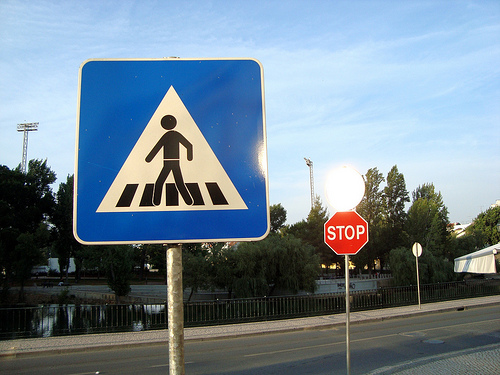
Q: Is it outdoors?
A: Yes, it is outdoors.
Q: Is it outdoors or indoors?
A: It is outdoors.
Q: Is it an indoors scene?
A: No, it is outdoors.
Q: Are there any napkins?
A: No, there are no napkins.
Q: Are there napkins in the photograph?
A: No, there are no napkins.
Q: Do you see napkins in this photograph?
A: No, there are no napkins.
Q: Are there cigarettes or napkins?
A: No, there are no napkins or cigarettes.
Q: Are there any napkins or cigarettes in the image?
A: No, there are no napkins or cigarettes.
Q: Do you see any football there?
A: No, there are no footballs.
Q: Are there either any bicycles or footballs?
A: No, there are no footballs or bicycles.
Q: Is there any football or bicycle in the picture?
A: No, there are no footballs or bicycles.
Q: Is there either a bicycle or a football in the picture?
A: No, there are no footballs or bicycles.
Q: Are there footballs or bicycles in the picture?
A: No, there are no footballs or bicycles.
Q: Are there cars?
A: No, there are no cars.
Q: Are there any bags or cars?
A: No, there are no cars or bags.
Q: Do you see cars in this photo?
A: No, there are no cars.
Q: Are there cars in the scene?
A: No, there are no cars.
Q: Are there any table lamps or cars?
A: No, there are no cars or table lamps.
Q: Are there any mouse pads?
A: No, there are no mouse pads.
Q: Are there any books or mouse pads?
A: No, there are no mouse pads or books.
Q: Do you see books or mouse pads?
A: No, there are no mouse pads or books.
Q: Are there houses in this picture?
A: No, there are no houses.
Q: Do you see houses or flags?
A: No, there are no houses or flags.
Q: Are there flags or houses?
A: No, there are no houses or flags.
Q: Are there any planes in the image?
A: No, there are no planes.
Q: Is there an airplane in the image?
A: No, there are no airplanes.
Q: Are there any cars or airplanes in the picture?
A: No, there are no airplanes or cars.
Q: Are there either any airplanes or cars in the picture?
A: No, there are no airplanes or cars.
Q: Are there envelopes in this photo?
A: No, there are no envelopes.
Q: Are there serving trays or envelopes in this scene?
A: No, there are no envelopes or serving trays.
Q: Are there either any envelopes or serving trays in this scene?
A: No, there are no envelopes or serving trays.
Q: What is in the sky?
A: The clouds are in the sky.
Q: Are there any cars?
A: No, there are no cars.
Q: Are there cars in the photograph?
A: No, there are no cars.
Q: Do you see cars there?
A: No, there are no cars.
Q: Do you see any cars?
A: No, there are no cars.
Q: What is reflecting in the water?
A: The tree is reflecting in the water.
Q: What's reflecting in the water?
A: The tree is reflecting in the water.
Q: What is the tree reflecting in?
A: The tree is reflecting in the water.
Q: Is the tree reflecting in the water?
A: Yes, the tree is reflecting in the water.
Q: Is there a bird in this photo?
A: No, there are no birds.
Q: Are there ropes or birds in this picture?
A: No, there are no birds or ropes.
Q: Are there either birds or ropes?
A: No, there are no birds or ropes.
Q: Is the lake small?
A: Yes, the lake is small.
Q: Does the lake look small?
A: Yes, the lake is small.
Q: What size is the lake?
A: The lake is small.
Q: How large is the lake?
A: The lake is small.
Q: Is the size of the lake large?
A: No, the lake is small.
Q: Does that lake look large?
A: No, the lake is small.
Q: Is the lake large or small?
A: The lake is small.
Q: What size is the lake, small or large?
A: The lake is small.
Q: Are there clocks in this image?
A: No, there are no clocks.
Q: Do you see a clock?
A: No, there are no clocks.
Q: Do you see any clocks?
A: No, there are no clocks.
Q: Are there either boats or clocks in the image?
A: No, there are no clocks or boats.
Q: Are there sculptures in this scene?
A: No, there are no sculptures.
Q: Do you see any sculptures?
A: No, there are no sculptures.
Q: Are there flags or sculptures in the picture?
A: No, there are no sculptures or flags.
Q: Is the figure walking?
A: Yes, the figure is walking.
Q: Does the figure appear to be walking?
A: Yes, the figure is walking.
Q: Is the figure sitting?
A: No, the figure is walking.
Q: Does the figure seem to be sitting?
A: No, the figure is walking.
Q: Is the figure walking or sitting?
A: The figure is walking.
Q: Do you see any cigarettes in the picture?
A: No, there are no cigarettes.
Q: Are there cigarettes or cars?
A: No, there are no cigarettes or cars.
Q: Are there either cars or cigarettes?
A: No, there are no cigarettes or cars.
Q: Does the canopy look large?
A: Yes, the canopy is large.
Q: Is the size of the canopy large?
A: Yes, the canopy is large.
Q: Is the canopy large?
A: Yes, the canopy is large.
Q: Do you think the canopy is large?
A: Yes, the canopy is large.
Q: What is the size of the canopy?
A: The canopy is large.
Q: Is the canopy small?
A: No, the canopy is large.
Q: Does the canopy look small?
A: No, the canopy is large.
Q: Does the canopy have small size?
A: No, the canopy is large.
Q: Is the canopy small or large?
A: The canopy is large.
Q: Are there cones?
A: No, there are no cones.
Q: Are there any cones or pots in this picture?
A: No, there are no cones or pots.